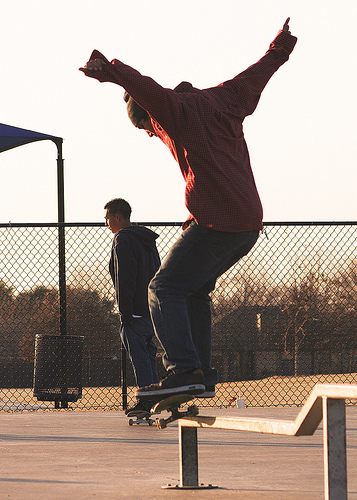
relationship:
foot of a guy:
[132, 364, 205, 397] [74, 15, 299, 402]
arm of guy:
[214, 10, 307, 125] [74, 15, 299, 402]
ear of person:
[111, 211, 121, 222] [104, 199, 162, 411]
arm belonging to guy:
[103, 54, 173, 122] [74, 15, 299, 402]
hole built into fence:
[292, 253, 299, 262] [279, 247, 342, 293]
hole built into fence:
[301, 258, 309, 266] [279, 247, 342, 293]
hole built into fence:
[315, 266, 324, 275] [279, 247, 342, 293]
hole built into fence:
[326, 253, 335, 262] [279, 247, 342, 293]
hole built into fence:
[294, 275, 303, 284] [279, 247, 342, 293]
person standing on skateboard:
[104, 199, 162, 411] [126, 407, 162, 425]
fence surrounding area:
[2, 217, 352, 412] [1, 406, 356, 498]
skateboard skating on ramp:
[149, 392, 200, 431] [187, 410, 274, 440]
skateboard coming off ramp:
[149, 392, 200, 431] [164, 384, 356, 496]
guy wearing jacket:
[74, 15, 299, 402] [176, 140, 255, 195]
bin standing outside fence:
[30, 332, 84, 402] [2, 217, 352, 412]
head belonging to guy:
[121, 90, 156, 137] [74, 15, 299, 402]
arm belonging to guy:
[84, 54, 173, 121] [74, 15, 299, 402]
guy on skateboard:
[74, 15, 299, 402] [76, 323, 263, 422]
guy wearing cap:
[74, 15, 299, 402] [119, 88, 154, 129]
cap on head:
[119, 88, 154, 129] [119, 89, 165, 148]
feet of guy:
[134, 367, 205, 399] [74, 15, 299, 402]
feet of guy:
[189, 375, 216, 396] [74, 15, 299, 402]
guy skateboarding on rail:
[74, 15, 299, 402] [174, 381, 350, 493]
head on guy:
[121, 90, 156, 137] [74, 15, 299, 402]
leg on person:
[141, 229, 221, 378] [70, 28, 319, 454]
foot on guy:
[132, 364, 205, 397] [74, 15, 299, 402]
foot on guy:
[192, 381, 215, 397] [74, 15, 299, 402]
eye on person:
[104, 215, 110, 221] [98, 195, 167, 414]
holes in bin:
[30, 329, 83, 401] [30, 332, 84, 402]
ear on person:
[115, 213, 120, 221] [153, 53, 330, 340]